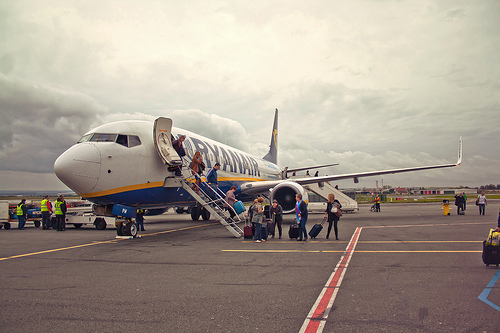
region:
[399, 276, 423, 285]
part of a airport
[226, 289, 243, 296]
section of the run way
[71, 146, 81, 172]
tip of a plane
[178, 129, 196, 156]
door of a plane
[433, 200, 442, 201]
part of a building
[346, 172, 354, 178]
wing of a plane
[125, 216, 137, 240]
wheel of a plane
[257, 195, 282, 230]
group of five people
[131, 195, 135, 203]
blue part on a plane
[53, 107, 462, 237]
white blue and yellow jet plane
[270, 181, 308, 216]
a jet's left wing engine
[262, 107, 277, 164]
tail of a jumbo jet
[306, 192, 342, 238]
a woman carrying a dark bag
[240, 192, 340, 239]
a group of passengers boarding a plane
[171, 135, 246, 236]
group of passengers leaving a plane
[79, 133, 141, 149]
windshield of a jet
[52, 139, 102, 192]
nose of a white jet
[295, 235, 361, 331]
red line on a runway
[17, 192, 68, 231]
workers at an airport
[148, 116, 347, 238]
people stepping off of airplane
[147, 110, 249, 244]
passengers walking out of airplane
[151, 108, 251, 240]
individuals walking down airplane steps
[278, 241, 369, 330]
red stripe on airplane runway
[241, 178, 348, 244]
people in front of airplane engine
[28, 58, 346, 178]
white airplane in front of clouds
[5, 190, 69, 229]
airplane crew standing wearing bright vests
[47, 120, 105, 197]
white nose of airplane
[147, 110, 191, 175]
white open door of airplane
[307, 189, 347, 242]
person standing while holding on to luggage handle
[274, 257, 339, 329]
A red line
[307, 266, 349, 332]
A red line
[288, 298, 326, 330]
A red line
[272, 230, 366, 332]
A red line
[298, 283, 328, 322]
A red line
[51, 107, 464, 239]
Ryanair jet on taxiway.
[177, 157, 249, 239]
Stairs leading up to Ryanair jet.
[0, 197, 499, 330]
Airport taxiway.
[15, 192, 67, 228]
Three baggage handlers unloading the jet.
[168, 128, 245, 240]
Passengers exiting plane and going down the stairs.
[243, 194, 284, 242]
Group of three people checking their belongings.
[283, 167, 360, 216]
Stairway ramp at the back of plane with passengers exiting plane.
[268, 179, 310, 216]
One of two large engines of the Ryanair jet.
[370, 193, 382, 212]
An airport employee observing the passengers leaving the plane.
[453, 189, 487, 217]
A group of three people heading for the airport gate.